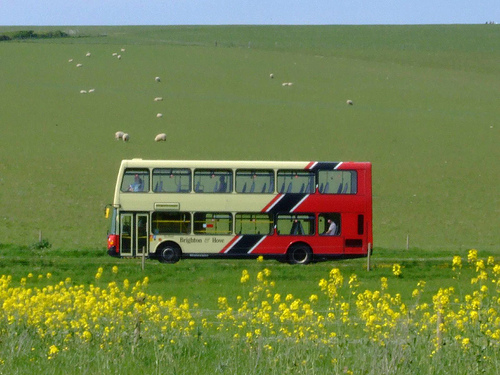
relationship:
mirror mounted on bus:
[102, 201, 120, 222] [97, 154, 378, 266]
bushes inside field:
[0, 25, 88, 48] [0, 25, 499, 250]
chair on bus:
[248, 180, 256, 193] [97, 154, 378, 266]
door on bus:
[116, 208, 151, 258] [97, 154, 378, 266]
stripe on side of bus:
[215, 157, 343, 258] [97, 154, 378, 266]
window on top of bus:
[119, 165, 151, 195] [97, 154, 378, 266]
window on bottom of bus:
[149, 207, 193, 237] [97, 154, 378, 266]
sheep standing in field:
[152, 130, 168, 144] [0, 25, 499, 250]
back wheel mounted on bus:
[284, 239, 313, 268] [97, 154, 378, 266]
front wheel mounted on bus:
[154, 238, 184, 266] [97, 154, 378, 266]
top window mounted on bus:
[233, 167, 277, 196] [97, 154, 378, 266]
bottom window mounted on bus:
[235, 211, 273, 236] [97, 154, 378, 266]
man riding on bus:
[319, 216, 339, 238] [97, 154, 378, 266]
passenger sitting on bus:
[215, 175, 230, 194] [97, 154, 378, 266]